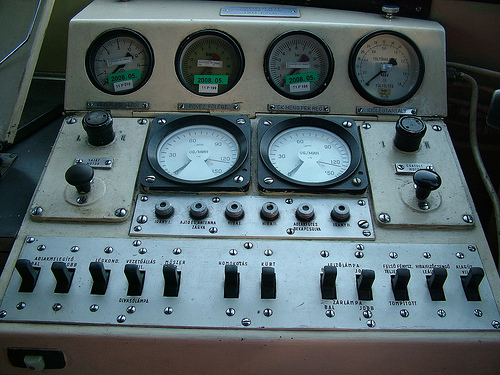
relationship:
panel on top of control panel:
[220, 0, 303, 20] [0, 0, 498, 374]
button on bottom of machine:
[17, 354, 64, 371] [6, 14, 498, 372]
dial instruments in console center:
[151, 117, 368, 194] [0, 1, 500, 373]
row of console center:
[14, 257, 485, 302] [0, 1, 500, 373]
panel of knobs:
[4, 240, 494, 322] [391, 263, 413, 293]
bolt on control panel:
[91, 306, 96, 313] [0, 0, 498, 374]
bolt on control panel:
[117, 315, 124, 323] [0, 0, 498, 374]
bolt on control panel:
[226, 311, 232, 318] [0, 0, 498, 374]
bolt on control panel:
[326, 312, 332, 318] [0, 0, 498, 374]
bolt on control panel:
[401, 311, 407, 317] [0, 0, 498, 374]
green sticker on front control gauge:
[282, 72, 324, 87] [262, 27, 333, 99]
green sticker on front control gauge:
[192, 70, 229, 87] [172, 27, 246, 99]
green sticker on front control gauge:
[102, 68, 145, 86] [82, 25, 154, 93]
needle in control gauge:
[360, 67, 386, 90] [346, 30, 425, 104]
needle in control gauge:
[284, 52, 306, 86] [262, 27, 333, 99]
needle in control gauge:
[105, 57, 125, 84] [82, 25, 154, 93]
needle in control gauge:
[192, 51, 219, 86] [172, 27, 246, 99]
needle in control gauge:
[287, 146, 312, 174] [260, 110, 360, 189]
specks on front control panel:
[215, 335, 295, 349] [0, 0, 498, 374]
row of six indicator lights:
[153, 199, 351, 223] [154, 200, 173, 220]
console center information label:
[0, 1, 500, 373] [218, 4, 301, 19]